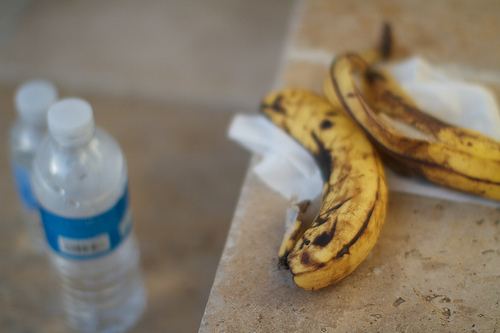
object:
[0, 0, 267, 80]
ground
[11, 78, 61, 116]
cap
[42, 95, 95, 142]
cap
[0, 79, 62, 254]
bottle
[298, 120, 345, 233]
brown lines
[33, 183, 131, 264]
label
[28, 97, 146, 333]
water bottle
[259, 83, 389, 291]
banana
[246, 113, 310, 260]
stem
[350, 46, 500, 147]
stem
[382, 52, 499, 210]
napkin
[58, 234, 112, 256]
bar code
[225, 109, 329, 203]
bag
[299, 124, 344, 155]
bruise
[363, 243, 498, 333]
stone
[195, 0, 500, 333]
counter top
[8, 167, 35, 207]
label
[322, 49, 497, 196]
banana